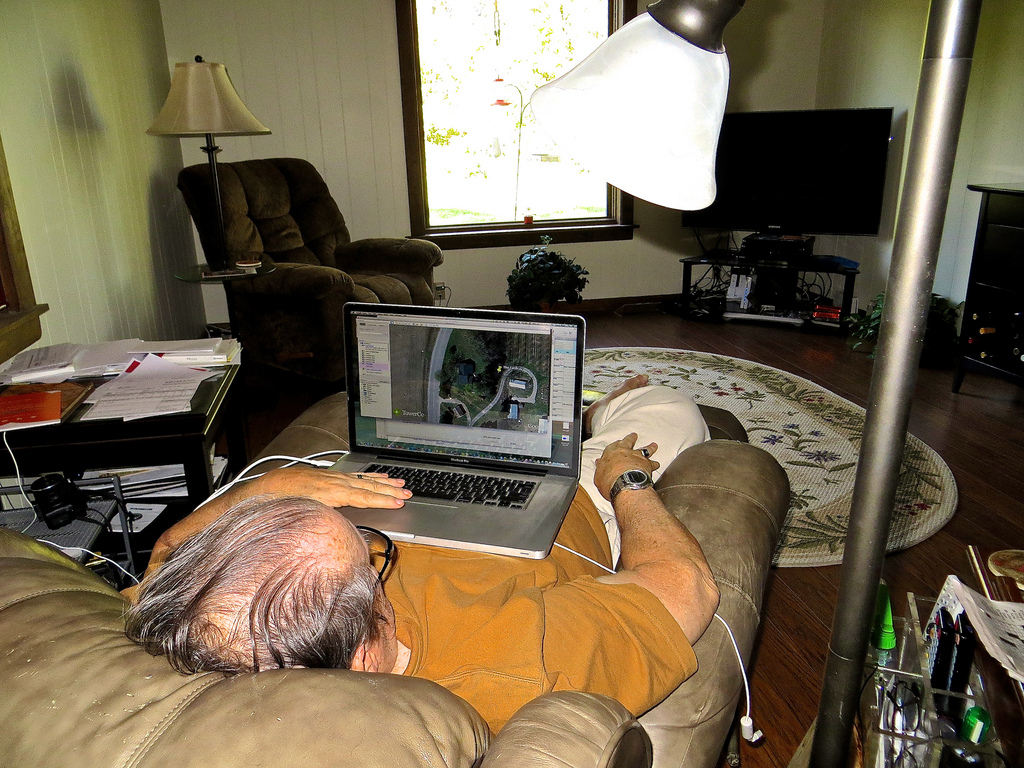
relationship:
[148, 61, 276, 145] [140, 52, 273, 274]
lampshade covering lamp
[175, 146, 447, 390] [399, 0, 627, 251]
recliner near window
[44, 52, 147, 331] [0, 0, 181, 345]
shadow projected onto wall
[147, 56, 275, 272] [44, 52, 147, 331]
lamp has shadow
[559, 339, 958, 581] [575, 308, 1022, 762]
area rug covering floor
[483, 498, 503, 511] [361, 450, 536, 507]
key on a keyboard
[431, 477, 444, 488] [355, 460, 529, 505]
key on a keyboard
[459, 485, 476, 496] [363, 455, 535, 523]
key on a keyboard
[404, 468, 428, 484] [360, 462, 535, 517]
key on a keyboard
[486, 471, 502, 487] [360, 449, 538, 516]
key on a keyboard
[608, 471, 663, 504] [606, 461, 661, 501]
watch on a wrist